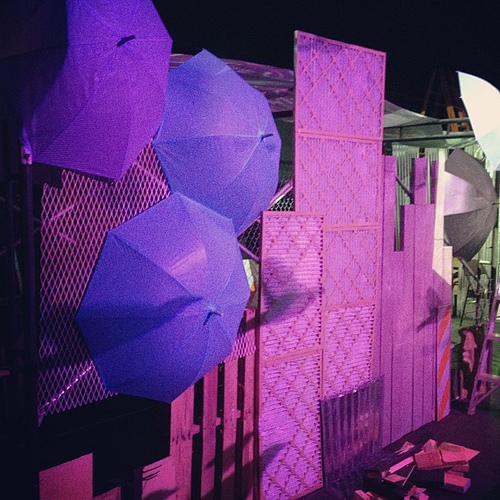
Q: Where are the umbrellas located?
A: The wall.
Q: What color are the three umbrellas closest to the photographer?
A: Blue.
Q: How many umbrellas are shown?
A: Five.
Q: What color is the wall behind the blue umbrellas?
A: Purple.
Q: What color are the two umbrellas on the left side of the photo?
A: Black and white.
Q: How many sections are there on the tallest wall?
A: Four.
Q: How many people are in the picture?
A: None.